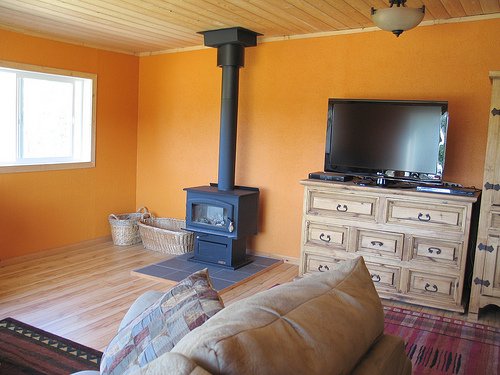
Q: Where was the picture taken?
A: In a house.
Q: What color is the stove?
A: Black.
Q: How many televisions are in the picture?
A: One.